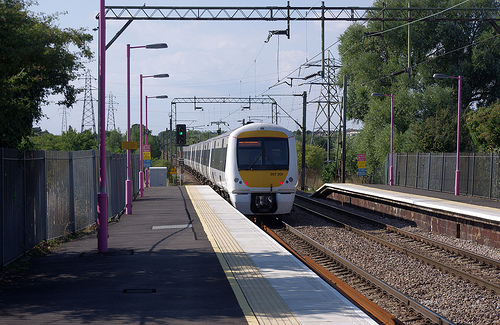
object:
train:
[178, 122, 303, 220]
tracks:
[294, 190, 499, 324]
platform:
[0, 184, 383, 324]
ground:
[0, 185, 386, 325]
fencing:
[0, 143, 152, 272]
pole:
[452, 78, 468, 197]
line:
[181, 181, 263, 325]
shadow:
[0, 247, 368, 324]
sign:
[175, 123, 188, 146]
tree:
[0, 0, 104, 154]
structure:
[148, 166, 169, 187]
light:
[368, 91, 389, 100]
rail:
[255, 216, 454, 324]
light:
[244, 181, 249, 186]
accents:
[235, 129, 289, 188]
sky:
[10, 2, 379, 140]